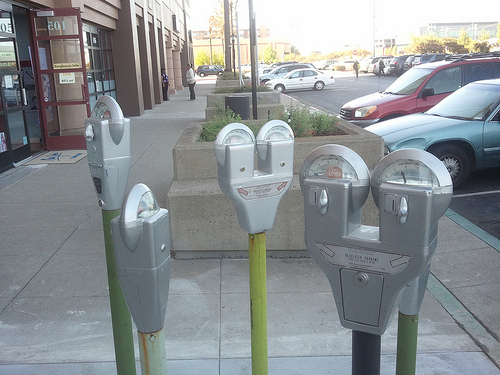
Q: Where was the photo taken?
A: It was taken at the sidewalk.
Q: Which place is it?
A: It is a sidewalk.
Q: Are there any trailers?
A: No, there are no trailers.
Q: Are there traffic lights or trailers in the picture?
A: No, there are no trailers or traffic lights.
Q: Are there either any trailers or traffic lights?
A: No, there are no trailers or traffic lights.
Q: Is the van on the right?
A: Yes, the van is on the right of the image.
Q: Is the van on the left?
A: No, the van is on the right of the image.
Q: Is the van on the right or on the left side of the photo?
A: The van is on the right of the image.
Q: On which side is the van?
A: The van is on the right of the image.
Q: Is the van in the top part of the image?
A: Yes, the van is in the top of the image.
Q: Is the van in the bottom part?
A: No, the van is in the top of the image.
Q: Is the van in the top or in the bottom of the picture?
A: The van is in the top of the image.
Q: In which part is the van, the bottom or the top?
A: The van is in the top of the image.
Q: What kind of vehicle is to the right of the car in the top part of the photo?
A: The vehicle is a van.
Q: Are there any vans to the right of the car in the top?
A: Yes, there is a van to the right of the car.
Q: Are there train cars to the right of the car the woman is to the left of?
A: No, there is a van to the right of the car.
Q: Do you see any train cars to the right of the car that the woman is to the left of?
A: No, there is a van to the right of the car.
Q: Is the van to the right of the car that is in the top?
A: Yes, the van is to the right of the car.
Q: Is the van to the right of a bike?
A: No, the van is to the right of the car.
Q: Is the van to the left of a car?
A: No, the van is to the right of a car.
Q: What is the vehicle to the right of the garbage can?
A: The vehicle is a van.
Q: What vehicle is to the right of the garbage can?
A: The vehicle is a van.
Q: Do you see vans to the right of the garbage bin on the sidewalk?
A: Yes, there is a van to the right of the trash bin.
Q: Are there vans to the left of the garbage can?
A: No, the van is to the right of the garbage can.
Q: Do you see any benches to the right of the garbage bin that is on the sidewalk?
A: No, there is a van to the right of the trashcan.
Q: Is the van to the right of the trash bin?
A: Yes, the van is to the right of the trash bin.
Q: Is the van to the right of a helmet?
A: No, the van is to the right of the trash bin.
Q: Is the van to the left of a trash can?
A: No, the van is to the right of a trash can.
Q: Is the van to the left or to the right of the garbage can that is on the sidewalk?
A: The van is to the right of the garbage bin.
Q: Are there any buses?
A: No, there are no buses.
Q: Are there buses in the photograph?
A: No, there are no buses.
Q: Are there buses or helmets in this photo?
A: No, there are no buses or helmets.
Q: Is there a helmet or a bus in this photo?
A: No, there are no buses or helmets.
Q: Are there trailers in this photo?
A: No, there are no trailers.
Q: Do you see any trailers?
A: No, there are no trailers.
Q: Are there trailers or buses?
A: No, there are no trailers or buses.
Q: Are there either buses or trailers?
A: No, there are no trailers or buses.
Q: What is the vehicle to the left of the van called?
A: The vehicle is a car.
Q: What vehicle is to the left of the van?
A: The vehicle is a car.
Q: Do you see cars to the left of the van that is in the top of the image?
A: Yes, there is a car to the left of the van.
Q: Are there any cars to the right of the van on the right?
A: No, the car is to the left of the van.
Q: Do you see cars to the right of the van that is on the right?
A: No, the car is to the left of the van.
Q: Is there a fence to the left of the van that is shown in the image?
A: No, there is a car to the left of the van.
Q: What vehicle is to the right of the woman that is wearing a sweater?
A: The vehicle is a car.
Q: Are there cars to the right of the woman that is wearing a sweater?
A: Yes, there is a car to the right of the woman.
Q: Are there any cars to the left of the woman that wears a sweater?
A: No, the car is to the right of the woman.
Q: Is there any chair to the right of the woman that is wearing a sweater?
A: No, there is a car to the right of the woman.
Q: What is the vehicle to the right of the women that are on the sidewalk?
A: The vehicle is a car.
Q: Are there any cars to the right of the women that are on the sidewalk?
A: Yes, there is a car to the right of the women.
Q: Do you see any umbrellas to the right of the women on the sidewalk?
A: No, there is a car to the right of the women.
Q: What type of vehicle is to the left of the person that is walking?
A: The vehicle is a car.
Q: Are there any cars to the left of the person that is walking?
A: Yes, there is a car to the left of the person.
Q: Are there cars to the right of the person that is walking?
A: No, the car is to the left of the person.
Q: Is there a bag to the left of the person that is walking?
A: No, there is a car to the left of the person.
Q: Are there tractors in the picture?
A: No, there are no tractors.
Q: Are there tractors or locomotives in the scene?
A: No, there are no tractors or locomotives.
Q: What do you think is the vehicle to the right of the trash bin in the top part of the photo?
A: The vehicle is a car.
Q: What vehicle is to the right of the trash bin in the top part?
A: The vehicle is a car.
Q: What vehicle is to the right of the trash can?
A: The vehicle is a car.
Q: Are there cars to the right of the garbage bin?
A: Yes, there is a car to the right of the garbage bin.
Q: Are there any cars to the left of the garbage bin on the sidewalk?
A: No, the car is to the right of the trash bin.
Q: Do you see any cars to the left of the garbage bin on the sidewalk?
A: No, the car is to the right of the trash bin.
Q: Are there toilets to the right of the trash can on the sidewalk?
A: No, there is a car to the right of the trash can.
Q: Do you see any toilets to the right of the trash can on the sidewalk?
A: No, there is a car to the right of the trash can.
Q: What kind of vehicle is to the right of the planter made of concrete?
A: The vehicle is a car.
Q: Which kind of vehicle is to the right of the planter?
A: The vehicle is a car.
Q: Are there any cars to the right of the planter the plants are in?
A: Yes, there is a car to the right of the planter.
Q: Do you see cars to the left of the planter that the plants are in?
A: No, the car is to the right of the planter.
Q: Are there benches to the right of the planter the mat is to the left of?
A: No, there is a car to the right of the planter.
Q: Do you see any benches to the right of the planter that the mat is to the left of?
A: No, there is a car to the right of the planter.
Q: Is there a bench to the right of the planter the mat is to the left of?
A: No, there is a car to the right of the planter.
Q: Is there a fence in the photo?
A: No, there are no fences.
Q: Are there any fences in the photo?
A: No, there are no fences.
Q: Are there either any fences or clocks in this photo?
A: No, there are no fences or clocks.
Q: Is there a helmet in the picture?
A: No, there are no helmets.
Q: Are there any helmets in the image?
A: No, there are no helmets.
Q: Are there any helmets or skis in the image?
A: No, there are no helmets or skis.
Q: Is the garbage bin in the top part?
A: Yes, the garbage bin is in the top of the image.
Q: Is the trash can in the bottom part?
A: No, the trash can is in the top of the image.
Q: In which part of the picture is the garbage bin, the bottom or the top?
A: The garbage bin is in the top of the image.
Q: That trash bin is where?
A: The trash bin is on the side walk.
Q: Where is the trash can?
A: The trash bin is on the side walk.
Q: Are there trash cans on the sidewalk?
A: Yes, there is a trash can on the sidewalk.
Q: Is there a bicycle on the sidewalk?
A: No, there is a trash can on the sidewalk.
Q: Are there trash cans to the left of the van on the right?
A: Yes, there is a trash can to the left of the van.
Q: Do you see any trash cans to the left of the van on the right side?
A: Yes, there is a trash can to the left of the van.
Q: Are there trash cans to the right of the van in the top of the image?
A: No, the trash can is to the left of the van.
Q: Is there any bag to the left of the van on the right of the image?
A: No, there is a trash can to the left of the van.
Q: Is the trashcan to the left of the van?
A: Yes, the trashcan is to the left of the van.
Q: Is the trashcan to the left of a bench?
A: No, the trashcan is to the left of the van.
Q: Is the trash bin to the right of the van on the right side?
A: No, the trash bin is to the left of the van.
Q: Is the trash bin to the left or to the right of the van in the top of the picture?
A: The trash bin is to the left of the van.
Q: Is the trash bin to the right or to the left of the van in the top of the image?
A: The trash bin is to the left of the van.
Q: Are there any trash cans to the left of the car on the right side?
A: Yes, there is a trash can to the left of the car.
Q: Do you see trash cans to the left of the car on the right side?
A: Yes, there is a trash can to the left of the car.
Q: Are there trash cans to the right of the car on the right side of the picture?
A: No, the trash can is to the left of the car.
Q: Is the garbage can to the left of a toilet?
A: No, the garbage can is to the left of the car.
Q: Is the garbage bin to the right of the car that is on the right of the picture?
A: No, the garbage bin is to the left of the car.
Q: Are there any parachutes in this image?
A: No, there are no parachutes.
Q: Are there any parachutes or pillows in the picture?
A: No, there are no parachutes or pillows.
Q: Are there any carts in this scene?
A: No, there are no carts.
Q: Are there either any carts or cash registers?
A: No, there are no carts or cash registers.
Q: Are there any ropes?
A: No, there are no ropes.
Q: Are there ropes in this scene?
A: No, there are no ropes.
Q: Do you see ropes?
A: No, there are no ropes.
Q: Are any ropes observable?
A: No, there are no ropes.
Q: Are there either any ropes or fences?
A: No, there are no ropes or fences.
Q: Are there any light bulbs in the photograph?
A: No, there are no light bulbs.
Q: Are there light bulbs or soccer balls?
A: No, there are no light bulbs or soccer balls.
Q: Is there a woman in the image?
A: Yes, there is a woman.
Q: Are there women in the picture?
A: Yes, there is a woman.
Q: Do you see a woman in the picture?
A: Yes, there is a woman.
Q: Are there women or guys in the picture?
A: Yes, there is a woman.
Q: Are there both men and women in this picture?
A: Yes, there are both a woman and a man.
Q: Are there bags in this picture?
A: No, there are no bags.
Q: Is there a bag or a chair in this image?
A: No, there are no bags or chairs.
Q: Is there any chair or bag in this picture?
A: No, there are no bags or chairs.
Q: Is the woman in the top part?
A: Yes, the woman is in the top of the image.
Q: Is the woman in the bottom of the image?
A: No, the woman is in the top of the image.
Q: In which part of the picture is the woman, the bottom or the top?
A: The woman is in the top of the image.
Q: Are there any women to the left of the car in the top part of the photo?
A: Yes, there is a woman to the left of the car.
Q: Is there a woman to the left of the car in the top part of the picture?
A: Yes, there is a woman to the left of the car.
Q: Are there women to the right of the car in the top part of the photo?
A: No, the woman is to the left of the car.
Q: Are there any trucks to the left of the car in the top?
A: No, there is a woman to the left of the car.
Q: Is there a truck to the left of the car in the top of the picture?
A: No, there is a woman to the left of the car.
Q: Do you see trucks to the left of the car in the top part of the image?
A: No, there is a woman to the left of the car.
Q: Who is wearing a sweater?
A: The woman is wearing a sweater.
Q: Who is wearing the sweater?
A: The woman is wearing a sweater.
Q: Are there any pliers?
A: No, there are no pliers.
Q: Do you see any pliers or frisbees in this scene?
A: No, there are no pliers or frisbees.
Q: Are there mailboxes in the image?
A: No, there are no mailboxes.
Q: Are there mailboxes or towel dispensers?
A: No, there are no mailboxes or towel dispensers.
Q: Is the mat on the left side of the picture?
A: Yes, the mat is on the left of the image.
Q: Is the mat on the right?
A: No, the mat is on the left of the image.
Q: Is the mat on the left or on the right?
A: The mat is on the left of the image.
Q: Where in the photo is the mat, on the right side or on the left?
A: The mat is on the left of the image.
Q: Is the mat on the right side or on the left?
A: The mat is on the left of the image.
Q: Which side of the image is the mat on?
A: The mat is on the left of the image.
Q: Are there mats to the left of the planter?
A: Yes, there is a mat to the left of the planter.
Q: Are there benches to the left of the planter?
A: No, there is a mat to the left of the planter.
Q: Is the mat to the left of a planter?
A: Yes, the mat is to the left of a planter.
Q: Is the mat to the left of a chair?
A: No, the mat is to the left of a planter.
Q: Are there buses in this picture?
A: No, there are no buses.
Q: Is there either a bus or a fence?
A: No, there are no buses or fences.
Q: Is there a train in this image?
A: No, there are no trains.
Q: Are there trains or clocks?
A: No, there are no trains or clocks.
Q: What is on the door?
A: The number is on the door.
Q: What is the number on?
A: The number is on the door.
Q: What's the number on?
A: The number is on the door.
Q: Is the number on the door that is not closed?
A: Yes, the number is on the door.